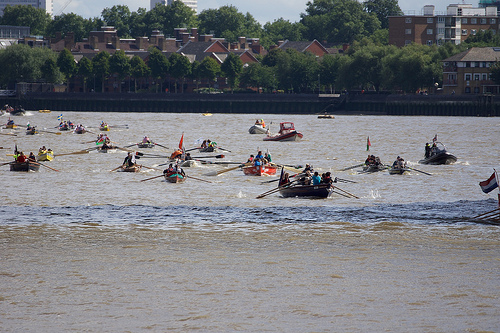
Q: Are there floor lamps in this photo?
A: No, there are no floor lamps.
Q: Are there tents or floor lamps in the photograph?
A: No, there are no floor lamps or tents.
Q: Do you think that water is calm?
A: Yes, the water is calm.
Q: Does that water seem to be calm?
A: Yes, the water is calm.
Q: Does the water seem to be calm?
A: Yes, the water is calm.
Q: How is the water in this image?
A: The water is calm.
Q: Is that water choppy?
A: No, the water is calm.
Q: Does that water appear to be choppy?
A: No, the water is calm.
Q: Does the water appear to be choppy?
A: No, the water is calm.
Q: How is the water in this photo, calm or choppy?
A: The water is calm.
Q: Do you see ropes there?
A: No, there are no ropes.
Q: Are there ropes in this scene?
A: No, there are no ropes.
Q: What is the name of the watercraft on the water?
A: The watercraft is boats.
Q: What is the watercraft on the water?
A: The watercraft is boats.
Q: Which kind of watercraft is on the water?
A: The watercraft is boats.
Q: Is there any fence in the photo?
A: No, there are no fences.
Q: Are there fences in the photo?
A: No, there are no fences.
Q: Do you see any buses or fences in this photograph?
A: No, there are no fences or buses.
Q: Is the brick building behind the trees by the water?
A: Yes, the building is behind the trees.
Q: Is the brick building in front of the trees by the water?
A: No, the building is behind the trees.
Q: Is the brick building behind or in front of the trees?
A: The building is behind the trees.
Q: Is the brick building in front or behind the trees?
A: The building is behind the trees.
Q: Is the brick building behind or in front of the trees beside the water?
A: The building is behind the trees.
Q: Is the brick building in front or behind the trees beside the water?
A: The building is behind the trees.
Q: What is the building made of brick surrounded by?
A: The building is surrounded by the trees.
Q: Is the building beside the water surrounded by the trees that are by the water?
A: Yes, the building is surrounded by the trees.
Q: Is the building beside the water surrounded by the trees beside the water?
A: Yes, the building is surrounded by the trees.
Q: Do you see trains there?
A: No, there are no trains.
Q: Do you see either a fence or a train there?
A: No, there are no trains or fences.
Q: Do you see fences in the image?
A: No, there are no fences.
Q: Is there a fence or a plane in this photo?
A: No, there are no fences or airplanes.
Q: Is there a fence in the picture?
A: No, there are no fences.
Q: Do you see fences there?
A: No, there are no fences.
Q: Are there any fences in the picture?
A: No, there are no fences.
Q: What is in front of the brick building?
A: The trees are in front of the building.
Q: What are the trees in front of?
A: The trees are in front of the building.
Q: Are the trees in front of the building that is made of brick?
A: Yes, the trees are in front of the building.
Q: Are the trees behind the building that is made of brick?
A: No, the trees are in front of the building.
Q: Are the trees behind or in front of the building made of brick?
A: The trees are in front of the building.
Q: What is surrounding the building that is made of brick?
A: The trees are surrounding the building.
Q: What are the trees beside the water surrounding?
A: The trees are surrounding the building.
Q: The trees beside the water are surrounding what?
A: The trees are surrounding the building.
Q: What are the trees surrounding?
A: The trees are surrounding the building.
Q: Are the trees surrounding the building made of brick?
A: Yes, the trees are surrounding the building.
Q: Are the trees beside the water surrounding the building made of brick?
A: Yes, the trees are surrounding the building.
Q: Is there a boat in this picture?
A: Yes, there is a boat.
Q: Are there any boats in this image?
A: Yes, there is a boat.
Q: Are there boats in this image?
A: Yes, there is a boat.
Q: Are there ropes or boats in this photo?
A: Yes, there is a boat.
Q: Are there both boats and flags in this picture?
A: Yes, there are both a boat and a flag.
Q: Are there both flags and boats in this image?
A: Yes, there are both a boat and a flag.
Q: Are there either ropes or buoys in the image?
A: No, there are no ropes or buoys.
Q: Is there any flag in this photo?
A: Yes, there is a flag.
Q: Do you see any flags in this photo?
A: Yes, there is a flag.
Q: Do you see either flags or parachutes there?
A: Yes, there is a flag.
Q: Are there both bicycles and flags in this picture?
A: No, there is a flag but no bicycles.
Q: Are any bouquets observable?
A: No, there are no bouquets.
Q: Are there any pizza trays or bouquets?
A: No, there are no bouquets or pizza trays.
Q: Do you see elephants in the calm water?
A: No, there is a flag in the water.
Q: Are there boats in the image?
A: Yes, there is a boat.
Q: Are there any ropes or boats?
A: Yes, there is a boat.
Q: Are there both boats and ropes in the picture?
A: No, there is a boat but no ropes.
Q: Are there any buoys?
A: No, there are no buoys.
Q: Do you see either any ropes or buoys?
A: No, there are no buoys or ropes.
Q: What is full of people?
A: The boat is full of people.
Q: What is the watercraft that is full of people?
A: The watercraft is a boat.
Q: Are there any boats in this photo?
A: Yes, there is a boat.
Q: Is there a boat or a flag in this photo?
A: Yes, there is a boat.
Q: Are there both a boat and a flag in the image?
A: Yes, there are both a boat and a flag.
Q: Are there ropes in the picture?
A: No, there are no ropes.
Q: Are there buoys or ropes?
A: No, there are no ropes or buoys.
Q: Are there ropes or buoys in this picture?
A: No, there are no ropes or buoys.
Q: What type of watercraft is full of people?
A: The watercraft is a boat.